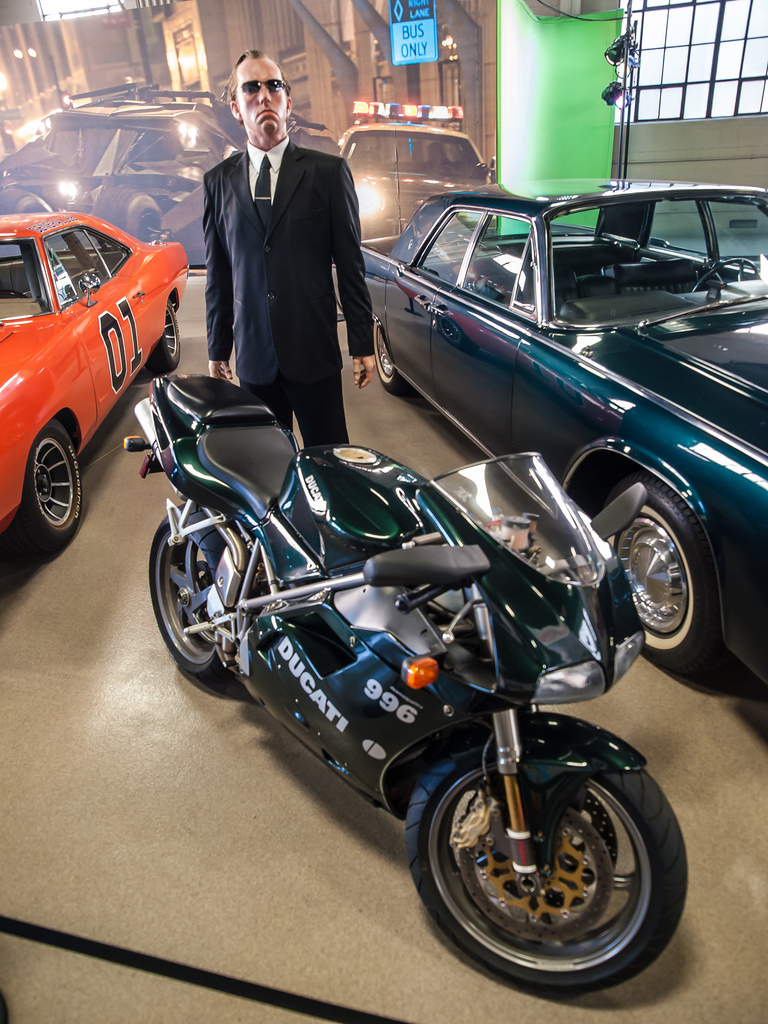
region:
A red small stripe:
[514, 840, 528, 866]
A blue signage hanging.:
[387, 0, 439, 66]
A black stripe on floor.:
[1, 913, 410, 1022]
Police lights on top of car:
[348, 99, 470, 129]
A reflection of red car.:
[389, 276, 623, 439]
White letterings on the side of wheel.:
[65, 440, 83, 517]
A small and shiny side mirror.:
[76, 271, 102, 307]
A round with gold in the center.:
[331, 445, 378, 465]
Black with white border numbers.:
[95, 294, 143, 393]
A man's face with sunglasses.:
[232, 56, 286, 139]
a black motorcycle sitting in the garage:
[119, 372, 698, 994]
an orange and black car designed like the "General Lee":
[0, 205, 192, 559]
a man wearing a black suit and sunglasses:
[200, 50, 384, 452]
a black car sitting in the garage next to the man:
[346, 172, 766, 695]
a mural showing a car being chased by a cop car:
[7, 3, 495, 265]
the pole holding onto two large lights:
[598, 3, 646, 175]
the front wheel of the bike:
[402, 728, 686, 1001]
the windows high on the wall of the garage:
[622, 3, 766, 114]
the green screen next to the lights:
[494, 3, 621, 182]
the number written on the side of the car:
[88, 290, 149, 395]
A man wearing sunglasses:
[221, 43, 296, 152]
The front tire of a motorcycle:
[397, 709, 692, 1007]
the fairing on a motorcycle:
[425, 444, 635, 595]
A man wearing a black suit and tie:
[191, 44, 385, 402]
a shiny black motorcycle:
[143, 354, 694, 987]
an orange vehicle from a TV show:
[2, 204, 186, 582]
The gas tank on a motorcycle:
[273, 439, 445, 553]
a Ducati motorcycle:
[130, 370, 676, 998]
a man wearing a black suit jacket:
[202, 46, 380, 394]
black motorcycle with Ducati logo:
[114, 360, 695, 999]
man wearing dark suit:
[195, 62, 382, 452]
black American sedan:
[362, 173, 766, 695]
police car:
[335, 95, 518, 242]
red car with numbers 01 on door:
[0, 207, 194, 547]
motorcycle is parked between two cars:
[2, 177, 766, 989]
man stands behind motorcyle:
[120, 65, 696, 1012]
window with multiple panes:
[623, 62, 764, 121]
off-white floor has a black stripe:
[1, 905, 409, 1022]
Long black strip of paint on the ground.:
[175, 958, 206, 1001]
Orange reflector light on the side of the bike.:
[390, 659, 447, 688]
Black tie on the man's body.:
[253, 150, 281, 227]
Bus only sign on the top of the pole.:
[381, 0, 447, 70]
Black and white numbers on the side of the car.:
[97, 303, 143, 390]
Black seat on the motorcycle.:
[198, 418, 312, 494]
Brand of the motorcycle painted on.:
[276, 640, 358, 745]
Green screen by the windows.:
[507, 83, 548, 140]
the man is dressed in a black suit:
[208, 50, 378, 395]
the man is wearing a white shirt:
[216, 48, 309, 218]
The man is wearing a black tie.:
[248, 166, 277, 225]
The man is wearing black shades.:
[236, 77, 283, 93]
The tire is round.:
[414, 759, 692, 1000]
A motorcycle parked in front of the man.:
[162, 388, 706, 989]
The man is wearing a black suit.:
[200, 49, 389, 391]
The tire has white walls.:
[601, 489, 720, 668]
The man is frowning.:
[237, 97, 292, 132]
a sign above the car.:
[368, 3, 462, 75]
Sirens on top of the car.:
[346, 92, 475, 123]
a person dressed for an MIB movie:
[202, 49, 373, 456]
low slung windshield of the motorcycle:
[431, 448, 604, 598]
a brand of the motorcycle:
[277, 638, 347, 736]